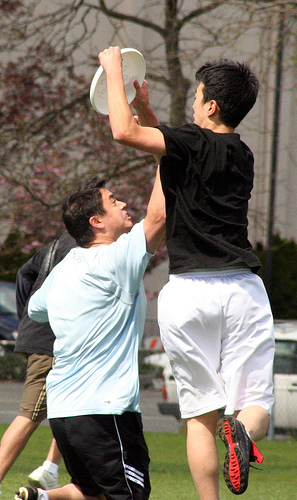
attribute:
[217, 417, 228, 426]
nub — red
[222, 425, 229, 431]
nub — red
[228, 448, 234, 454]
nub — red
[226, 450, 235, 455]
nub — red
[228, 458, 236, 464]
nub — red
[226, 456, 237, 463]
nub — red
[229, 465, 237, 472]
nub — red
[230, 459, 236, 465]
nub — red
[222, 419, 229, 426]
bump — red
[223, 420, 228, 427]
bump — red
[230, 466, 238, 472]
bump — red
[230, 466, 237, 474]
bump — red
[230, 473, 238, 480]
bump — red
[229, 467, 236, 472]
bump — red